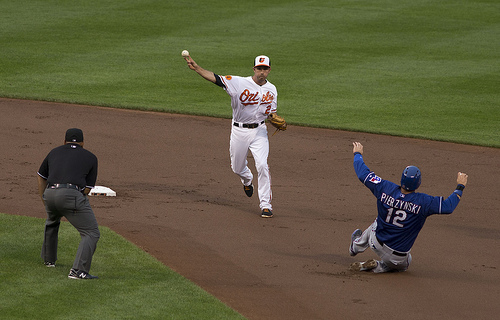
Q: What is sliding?
A: The baseball player.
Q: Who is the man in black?
A: The umpire.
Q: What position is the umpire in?
A: Hunched over.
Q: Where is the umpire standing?
A: On the grass.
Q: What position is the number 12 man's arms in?
A: Up in the air.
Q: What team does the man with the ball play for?
A: The Orioles.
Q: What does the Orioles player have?
A: The baseball.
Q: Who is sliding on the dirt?
A: The baseball player.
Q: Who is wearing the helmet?
A: The player in the blue uniform.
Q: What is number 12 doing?
A: Sliding on the baseball field.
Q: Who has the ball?
A: The Orioles baseball player.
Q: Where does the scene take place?
A: At a baseball game.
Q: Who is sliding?
A: Player in blue.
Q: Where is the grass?
A: On the field.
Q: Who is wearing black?
A: Umpire.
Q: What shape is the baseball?
A: Round.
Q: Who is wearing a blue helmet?
A: Player in blue.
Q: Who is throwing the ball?
A: Player in white.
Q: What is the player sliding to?
A: Second base.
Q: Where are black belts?
A: Around player's waists.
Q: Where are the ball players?
A: On the field.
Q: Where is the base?
A: On the ground.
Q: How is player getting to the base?
A: By running.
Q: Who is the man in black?
A: The referee.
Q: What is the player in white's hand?
A: A baseball.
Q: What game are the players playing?
A: Baseball.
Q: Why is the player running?
A: To get to the base.